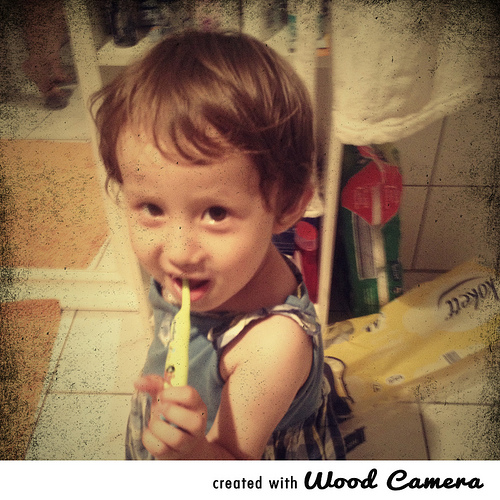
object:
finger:
[151, 388, 198, 408]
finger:
[152, 402, 208, 429]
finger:
[136, 421, 190, 446]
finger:
[135, 428, 167, 456]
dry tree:
[0, 33, 154, 458]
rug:
[6, 132, 123, 274]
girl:
[59, 66, 391, 462]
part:
[177, 387, 191, 403]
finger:
[154, 385, 203, 412]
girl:
[85, 32, 367, 464]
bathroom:
[0, 1, 499, 461]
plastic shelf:
[66, 0, 404, 214]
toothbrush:
[159, 270, 213, 404]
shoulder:
[231, 315, 314, 403]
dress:
[124, 256, 354, 458]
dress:
[149, 403, 359, 458]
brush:
[160, 275, 191, 390]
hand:
[131, 375, 208, 460]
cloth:
[126, 281, 358, 461]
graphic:
[331, 476, 361, 492]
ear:
[267, 150, 316, 237]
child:
[78, 64, 454, 499]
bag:
[315, 246, 498, 411]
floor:
[0, 278, 499, 460]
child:
[80, 18, 344, 495]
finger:
[153, 384, 203, 421]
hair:
[87, 26, 316, 225]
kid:
[95, 27, 340, 460]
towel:
[311, 39, 425, 193]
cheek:
[205, 233, 262, 277]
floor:
[5, 301, 127, 455]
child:
[80, 33, 331, 344]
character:
[160, 354, 181, 386]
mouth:
[162, 269, 216, 299]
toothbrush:
[168, 283, 194, 383]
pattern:
[133, 367, 350, 455]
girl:
[65, 27, 369, 436]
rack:
[311, 0, 411, 263]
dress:
[125, 283, 342, 456]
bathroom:
[24, 17, 457, 438]